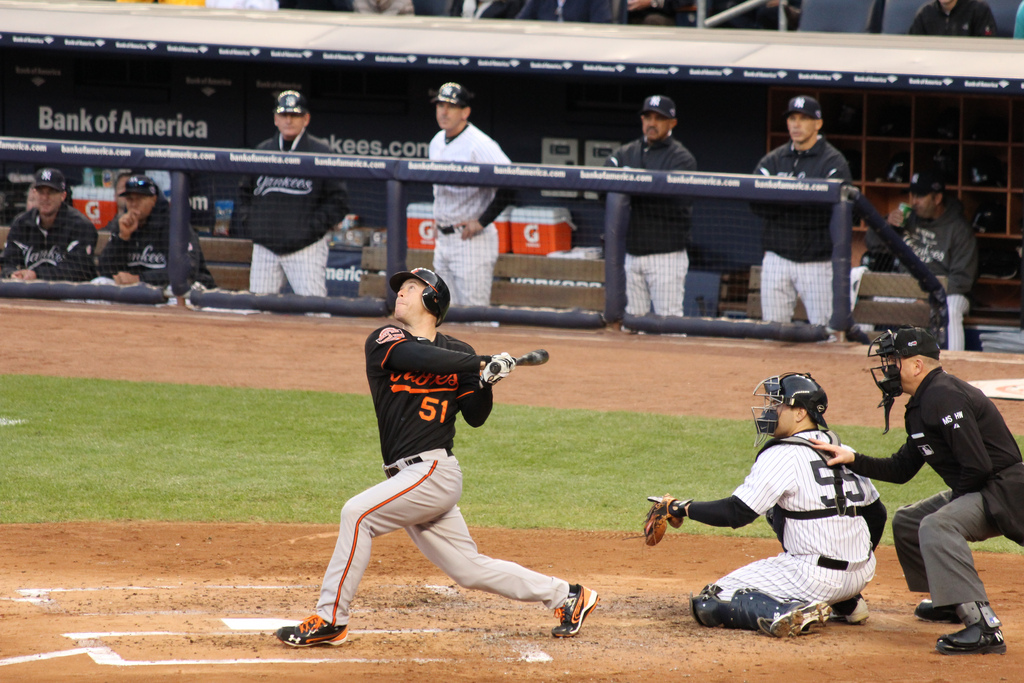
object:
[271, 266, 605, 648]
baseball player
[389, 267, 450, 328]
helmet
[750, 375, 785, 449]
face mask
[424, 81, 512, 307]
person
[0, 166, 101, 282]
person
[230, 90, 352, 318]
person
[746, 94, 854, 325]
person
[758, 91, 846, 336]
person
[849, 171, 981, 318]
person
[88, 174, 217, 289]
person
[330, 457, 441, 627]
stripe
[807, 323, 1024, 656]
man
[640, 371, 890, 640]
catcher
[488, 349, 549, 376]
baseball bat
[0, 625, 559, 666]
box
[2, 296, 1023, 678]
ground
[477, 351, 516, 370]
hand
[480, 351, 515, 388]
hand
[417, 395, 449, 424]
number 51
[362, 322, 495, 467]
uniform shirt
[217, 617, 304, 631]
home plate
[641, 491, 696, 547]
glove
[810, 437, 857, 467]
hand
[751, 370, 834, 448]
helmet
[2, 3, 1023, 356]
dugout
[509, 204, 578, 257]
cooler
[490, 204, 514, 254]
cooler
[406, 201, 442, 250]
cooler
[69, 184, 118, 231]
cooler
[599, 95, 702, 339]
person